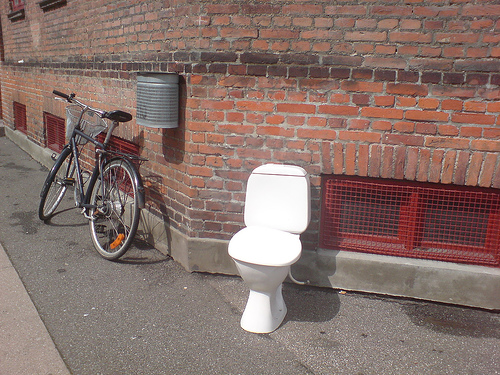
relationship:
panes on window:
[91, 130, 143, 190] [318, 173, 498, 284]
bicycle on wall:
[37, 83, 154, 270] [41, 33, 128, 120]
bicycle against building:
[37, 83, 154, 270] [1, 0, 491, 298]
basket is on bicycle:
[62, 109, 129, 141] [38, 120, 173, 244]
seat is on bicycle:
[90, 92, 137, 124] [15, 79, 172, 273]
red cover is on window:
[323, 180, 498, 267] [343, 191, 485, 244]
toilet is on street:
[222, 159, 317, 339] [0, 135, 499, 372]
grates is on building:
[321, 172, 498, 269] [1, 0, 491, 298]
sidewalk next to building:
[6, 159, 491, 369] [1, 0, 491, 298]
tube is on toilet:
[282, 265, 317, 291] [212, 140, 331, 350]